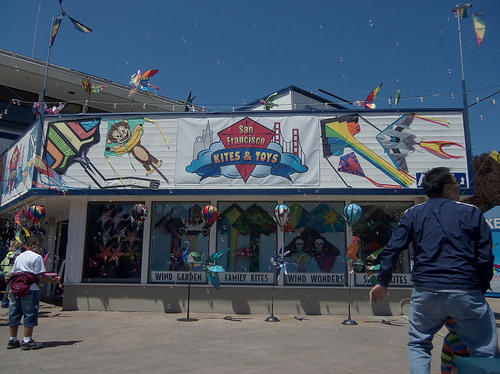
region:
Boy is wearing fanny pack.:
[3, 267, 56, 302]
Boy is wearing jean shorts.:
[6, 282, 44, 332]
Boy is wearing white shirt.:
[8, 250, 50, 295]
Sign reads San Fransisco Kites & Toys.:
[198, 118, 287, 178]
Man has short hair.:
[400, 164, 463, 209]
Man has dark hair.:
[418, 158, 460, 211]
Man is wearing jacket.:
[376, 193, 498, 304]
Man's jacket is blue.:
[361, 197, 498, 306]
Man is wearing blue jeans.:
[398, 284, 498, 372]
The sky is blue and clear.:
[0, 0, 499, 159]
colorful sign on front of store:
[56, 116, 434, 186]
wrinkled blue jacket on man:
[377, 195, 490, 302]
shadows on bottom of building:
[83, 288, 366, 320]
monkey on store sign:
[103, 112, 179, 177]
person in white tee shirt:
[8, 235, 51, 292]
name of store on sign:
[209, 120, 281, 178]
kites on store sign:
[312, 111, 451, 183]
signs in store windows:
[147, 266, 363, 288]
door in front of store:
[50, 210, 73, 310]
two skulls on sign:
[287, 231, 331, 258]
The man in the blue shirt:
[370, 164, 497, 372]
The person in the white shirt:
[0, 236, 61, 351]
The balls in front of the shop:
[25, 196, 364, 231]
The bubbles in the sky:
[14, 4, 483, 121]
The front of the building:
[0, 113, 475, 280]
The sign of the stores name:
[185, 113, 312, 183]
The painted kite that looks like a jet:
[374, 112, 466, 184]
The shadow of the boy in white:
[34, 334, 83, 355]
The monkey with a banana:
[102, 121, 177, 178]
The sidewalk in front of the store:
[7, 306, 499, 372]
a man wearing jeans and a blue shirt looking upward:
[360, 161, 499, 369]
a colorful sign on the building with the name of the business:
[178, 114, 333, 195]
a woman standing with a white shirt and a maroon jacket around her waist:
[0, 232, 57, 354]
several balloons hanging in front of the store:
[123, 203, 371, 242]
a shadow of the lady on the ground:
[29, 334, 86, 354]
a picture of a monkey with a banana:
[102, 124, 165, 183]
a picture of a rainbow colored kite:
[316, 113, 408, 186]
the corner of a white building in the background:
[264, 80, 325, 111]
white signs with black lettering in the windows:
[147, 267, 352, 286]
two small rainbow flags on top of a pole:
[450, 1, 493, 56]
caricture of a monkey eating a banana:
[104, 116, 175, 181]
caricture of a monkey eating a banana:
[92, 115, 164, 176]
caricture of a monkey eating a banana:
[105, 122, 156, 168]